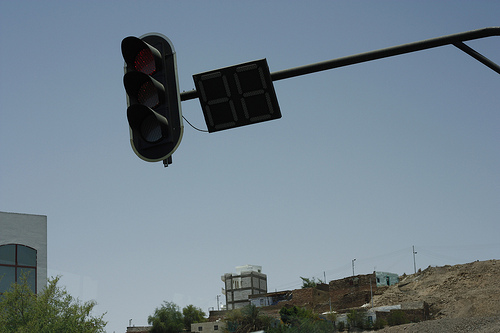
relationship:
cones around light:
[108, 18, 169, 176] [119, 32, 183, 169]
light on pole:
[119, 32, 183, 169] [280, 47, 478, 91]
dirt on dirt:
[380, 280, 481, 330] [427, 273, 499, 310]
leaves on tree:
[0, 278, 113, 332] [18, 271, 100, 331]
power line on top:
[346, 249, 409, 264] [323, 257, 489, 310]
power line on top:
[325, 259, 360, 273] [323, 257, 489, 310]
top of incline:
[323, 257, 489, 310] [344, 250, 498, 326]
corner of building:
[39, 210, 55, 300] [1, 208, 58, 324]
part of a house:
[238, 286, 270, 318] [221, 273, 284, 323]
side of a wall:
[1, 210, 18, 230] [3, 210, 44, 287]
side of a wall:
[230, 276, 250, 291] [219, 261, 264, 312]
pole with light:
[181, 35, 491, 86] [119, 32, 183, 169]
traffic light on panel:
[116, 28, 161, 70] [113, 28, 185, 169]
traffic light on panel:
[124, 65, 167, 108] [113, 28, 185, 169]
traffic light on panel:
[130, 103, 170, 152] [113, 28, 185, 169]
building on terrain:
[219, 264, 267, 313] [208, 276, 498, 330]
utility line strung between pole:
[357, 246, 404, 261] [346, 248, 360, 278]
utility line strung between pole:
[357, 256, 401, 266] [346, 248, 360, 278]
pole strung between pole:
[346, 248, 360, 278] [404, 237, 422, 276]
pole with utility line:
[407, 240, 423, 272] [353, 251, 403, 264]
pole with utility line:
[351, 258, 357, 276] [413, 245, 463, 265]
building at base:
[191, 320, 233, 333] [200, 305, 291, 330]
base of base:
[200, 305, 291, 330] [291, 259, 500, 333]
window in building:
[208, 321, 221, 330] [186, 306, 232, 330]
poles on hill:
[347, 246, 426, 275] [322, 256, 491, 321]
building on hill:
[219, 264, 267, 313] [224, 270, 409, 325]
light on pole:
[119, 32, 183, 169] [174, 58, 358, 109]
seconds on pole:
[190, 57, 283, 134] [174, 47, 390, 89]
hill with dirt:
[293, 254, 491, 324] [418, 270, 493, 309]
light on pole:
[119, 32, 183, 169] [176, 50, 376, 106]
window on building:
[1, 240, 39, 309] [0, 213, 53, 315]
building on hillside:
[219, 264, 267, 313] [187, 270, 439, 330]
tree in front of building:
[0, 267, 107, 332] [5, 210, 48, 310]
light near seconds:
[119, 32, 186, 174] [190, 57, 283, 134]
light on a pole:
[119, 32, 183, 169] [129, 2, 499, 109]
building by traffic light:
[218, 253, 284, 330] [91, 13, 212, 204]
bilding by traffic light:
[0, 183, 72, 329] [97, 16, 207, 188]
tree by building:
[0, 253, 151, 327] [9, 178, 91, 330]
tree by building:
[0, 267, 107, 332] [9, 178, 91, 330]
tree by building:
[0, 267, 107, 332] [3, 188, 129, 330]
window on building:
[0, 243, 38, 297] [1, 182, 85, 330]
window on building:
[0, 243, 38, 297] [0, 188, 94, 329]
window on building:
[0, 243, 38, 297] [0, 180, 69, 330]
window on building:
[12, 262, 43, 299] [0, 177, 60, 327]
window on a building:
[215, 284, 270, 313] [204, 253, 274, 323]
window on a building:
[207, 311, 226, 330] [178, 292, 227, 330]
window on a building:
[242, 280, 289, 316] [196, 238, 300, 328]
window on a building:
[335, 238, 416, 295] [359, 261, 402, 305]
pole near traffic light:
[189, 13, 499, 124] [79, 9, 192, 191]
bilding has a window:
[0, 211, 48, 332] [0, 231, 40, 318]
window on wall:
[0, 243, 38, 297] [0, 185, 73, 303]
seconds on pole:
[182, 39, 302, 137] [272, 10, 498, 90]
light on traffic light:
[119, 34, 163, 79] [110, 17, 196, 166]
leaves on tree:
[0, 250, 179, 327] [0, 267, 107, 332]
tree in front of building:
[0, 267, 107, 332] [0, 177, 60, 327]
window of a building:
[0, 243, 38, 297] [1, 212, 53, 324]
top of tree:
[10, 279, 83, 307] [0, 267, 107, 332]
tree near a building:
[0, 267, 107, 332] [0, 208, 45, 292]